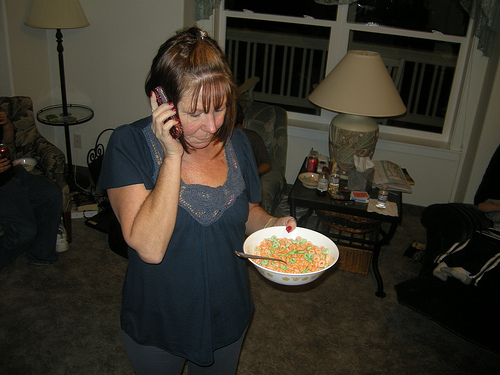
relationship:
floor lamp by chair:
[24, 9, 97, 216] [0, 88, 73, 248]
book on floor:
[62, 183, 118, 210] [20, 144, 499, 361]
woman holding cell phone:
[99, 24, 297, 373] [146, 77, 188, 152]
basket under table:
[320, 210, 379, 276] [285, 155, 402, 274]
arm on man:
[255, 167, 272, 176] [236, 105, 275, 169]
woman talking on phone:
[99, 24, 297, 373] [145, 80, 185, 139]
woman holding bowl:
[99, 24, 297, 373] [228, 215, 343, 287]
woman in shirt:
[99, 24, 297, 373] [97, 144, 299, 362]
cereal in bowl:
[260, 235, 327, 272] [236, 223, 341, 291]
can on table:
[292, 152, 327, 179] [270, 149, 417, 294]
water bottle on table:
[329, 157, 341, 197] [287, 152, 402, 297]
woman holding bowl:
[99, 24, 297, 373] [242, 225, 339, 285]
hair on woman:
[146, 18, 236, 139] [99, 24, 297, 373]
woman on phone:
[99, 24, 297, 373] [155, 86, 200, 149]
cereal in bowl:
[247, 224, 327, 274] [228, 215, 343, 287]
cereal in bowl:
[268, 241, 310, 269] [236, 223, 341, 291]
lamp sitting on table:
[306, 48, 408, 181] [287, 152, 402, 297]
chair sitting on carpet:
[392, 198, 499, 337] [242, 250, 462, 374]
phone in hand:
[155, 86, 200, 149] [147, 86, 195, 157]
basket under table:
[317, 207, 372, 235] [287, 152, 402, 297]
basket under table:
[332, 243, 374, 276] [287, 152, 402, 297]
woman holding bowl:
[99, 24, 297, 373] [243, 214, 340, 289]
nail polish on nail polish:
[286, 223, 295, 233] [286, 223, 295, 233]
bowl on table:
[296, 172, 321, 189] [287, 152, 402, 297]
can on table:
[292, 152, 327, 179] [287, 152, 402, 297]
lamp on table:
[306, 48, 408, 181] [287, 152, 402, 297]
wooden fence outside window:
[228, 27, 458, 129] [216, 0, 481, 150]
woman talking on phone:
[99, 24, 297, 373] [151, 82, 183, 139]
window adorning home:
[216, 0, 481, 150] [1, 2, 484, 372]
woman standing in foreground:
[99, 24, 297, 373] [0, 22, 484, 366]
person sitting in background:
[0, 102, 64, 291] [2, 3, 483, 302]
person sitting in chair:
[0, 102, 64, 291] [9, 86, 99, 257]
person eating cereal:
[0, 102, 64, 291] [13, 155, 36, 171]